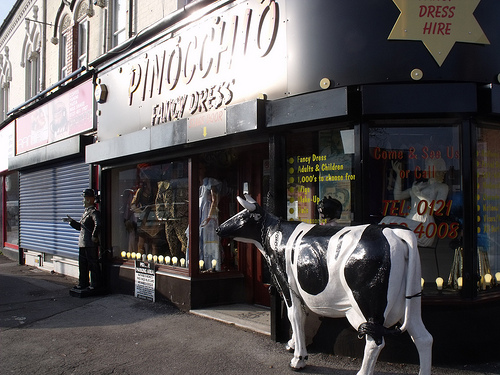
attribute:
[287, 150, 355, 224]
lettering — yellow